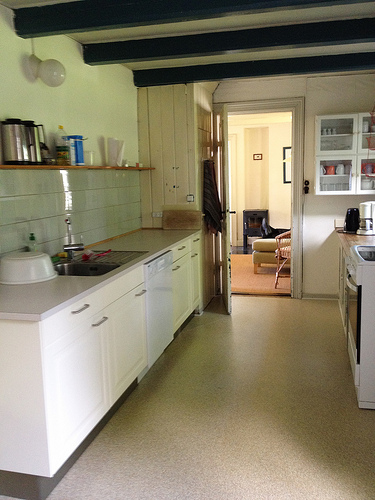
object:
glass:
[320, 118, 353, 151]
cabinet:
[313, 110, 374, 196]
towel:
[203, 160, 222, 236]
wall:
[146, 84, 178, 160]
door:
[218, 103, 237, 315]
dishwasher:
[143, 249, 174, 367]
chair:
[274, 230, 291, 289]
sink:
[54, 262, 121, 275]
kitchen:
[0, 0, 375, 500]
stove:
[344, 245, 375, 410]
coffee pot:
[0, 118, 50, 166]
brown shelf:
[0, 165, 157, 171]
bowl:
[0, 252, 58, 285]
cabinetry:
[0, 224, 203, 500]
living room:
[228, 109, 290, 295]